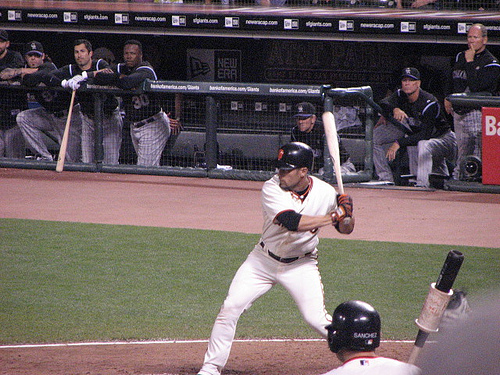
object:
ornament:
[277, 149, 283, 159]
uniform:
[242, 180, 356, 347]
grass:
[4, 232, 211, 340]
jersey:
[257, 172, 340, 262]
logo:
[272, 147, 284, 161]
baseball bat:
[317, 110, 355, 226]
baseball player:
[193, 110, 353, 375]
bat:
[53, 85, 76, 173]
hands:
[63, 75, 87, 90]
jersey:
[111, 56, 164, 130]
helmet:
[270, 139, 317, 171]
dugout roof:
[6, 1, 498, 48]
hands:
[327, 189, 357, 224]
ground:
[1, 165, 498, 373]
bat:
[404, 245, 466, 367]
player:
[0, 41, 61, 166]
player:
[59, 39, 122, 164]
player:
[94, 42, 170, 167]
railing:
[4, 78, 373, 178]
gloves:
[330, 192, 358, 229]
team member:
[367, 64, 458, 186]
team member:
[448, 21, 499, 189]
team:
[0, 43, 173, 168]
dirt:
[1, 168, 499, 373]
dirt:
[237, 346, 310, 372]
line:
[3, 327, 209, 348]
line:
[234, 330, 323, 347]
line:
[380, 328, 415, 347]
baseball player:
[313, 244, 463, 375]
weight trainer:
[414, 282, 454, 333]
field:
[1, 165, 497, 373]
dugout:
[2, 9, 492, 192]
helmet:
[321, 298, 384, 356]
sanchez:
[352, 328, 380, 341]